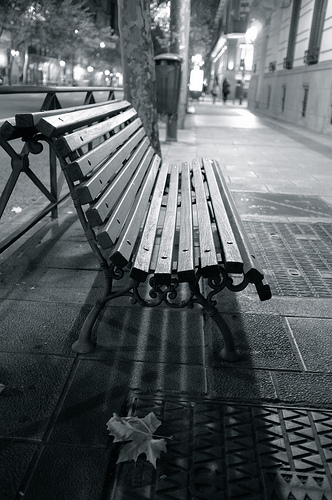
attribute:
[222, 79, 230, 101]
woman — walking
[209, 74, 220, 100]
woman — walking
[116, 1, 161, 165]
trunk — tree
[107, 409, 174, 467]
leaf — fallen, maple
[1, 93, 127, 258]
fence — metal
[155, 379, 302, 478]
hole — sewer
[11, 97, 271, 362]
bench — empty, iron, wooden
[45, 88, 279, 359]
bench — wooden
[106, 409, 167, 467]
leaf — light, colored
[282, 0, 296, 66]
bars — metal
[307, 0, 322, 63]
bars — metal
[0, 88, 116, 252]
fence — iron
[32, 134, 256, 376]
support — metal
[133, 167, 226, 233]
support — metal